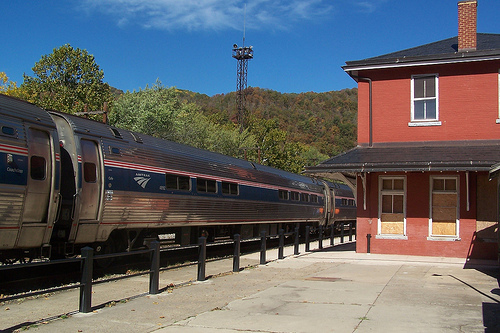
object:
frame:
[408, 74, 424, 99]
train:
[0, 93, 357, 271]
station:
[0, 228, 499, 333]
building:
[304, 0, 500, 259]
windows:
[391, 177, 403, 192]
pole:
[77, 244, 95, 314]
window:
[379, 195, 393, 214]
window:
[430, 179, 442, 193]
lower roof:
[303, 141, 500, 174]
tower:
[231, 2, 254, 120]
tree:
[29, 41, 108, 113]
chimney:
[458, 0, 476, 55]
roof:
[342, 31, 499, 68]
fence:
[0, 218, 355, 333]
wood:
[378, 221, 403, 236]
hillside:
[97, 78, 358, 160]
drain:
[357, 78, 373, 147]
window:
[423, 98, 437, 121]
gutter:
[339, 52, 496, 71]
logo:
[131, 173, 153, 189]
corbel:
[336, 171, 357, 203]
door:
[75, 134, 107, 223]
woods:
[430, 206, 460, 223]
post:
[150, 234, 161, 293]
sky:
[0, 0, 499, 97]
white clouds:
[75, 0, 339, 39]